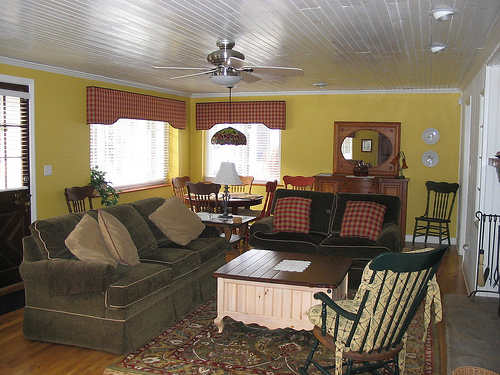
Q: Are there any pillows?
A: Yes, there are pillows.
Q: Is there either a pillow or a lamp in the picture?
A: Yes, there are pillows.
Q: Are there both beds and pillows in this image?
A: No, there are pillows but no beds.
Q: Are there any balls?
A: No, there are no balls.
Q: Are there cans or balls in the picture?
A: No, there are no balls or cans.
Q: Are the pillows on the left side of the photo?
A: Yes, the pillows are on the left of the image.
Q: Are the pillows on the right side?
A: No, the pillows are on the left of the image.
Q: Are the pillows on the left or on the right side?
A: The pillows are on the left of the image.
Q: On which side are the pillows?
A: The pillows are on the left of the image.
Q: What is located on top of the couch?
A: The pillows are on top of the couch.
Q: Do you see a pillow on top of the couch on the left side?
A: Yes, there are pillows on top of the couch.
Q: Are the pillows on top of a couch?
A: Yes, the pillows are on top of a couch.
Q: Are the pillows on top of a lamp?
A: No, the pillows are on top of a couch.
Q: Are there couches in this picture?
A: Yes, there is a couch.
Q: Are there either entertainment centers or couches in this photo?
A: Yes, there is a couch.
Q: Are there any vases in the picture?
A: No, there are no vases.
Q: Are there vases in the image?
A: No, there are no vases.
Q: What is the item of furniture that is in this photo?
A: The piece of furniture is a couch.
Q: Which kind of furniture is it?
A: The piece of furniture is a couch.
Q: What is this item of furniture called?
A: This is a couch.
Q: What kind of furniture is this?
A: This is a couch.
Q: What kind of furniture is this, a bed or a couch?
A: This is a couch.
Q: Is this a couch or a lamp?
A: This is a couch.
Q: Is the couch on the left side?
A: Yes, the couch is on the left of the image.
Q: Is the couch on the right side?
A: No, the couch is on the left of the image.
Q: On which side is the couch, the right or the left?
A: The couch is on the left of the image.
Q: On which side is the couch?
A: The couch is on the left of the image.